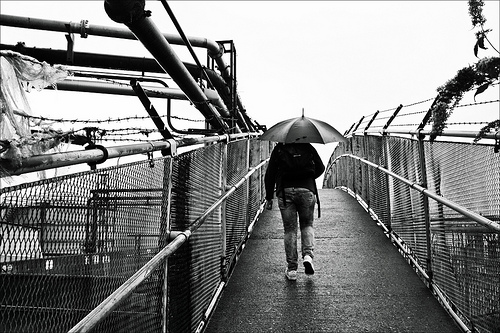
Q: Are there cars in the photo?
A: No, there are no cars.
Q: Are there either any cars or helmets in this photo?
A: No, there are no cars or helmets.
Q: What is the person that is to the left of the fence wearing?
A: The person is wearing jeans.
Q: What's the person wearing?
A: The person is wearing jeans.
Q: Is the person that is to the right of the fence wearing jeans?
A: Yes, the person is wearing jeans.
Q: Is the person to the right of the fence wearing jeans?
A: Yes, the person is wearing jeans.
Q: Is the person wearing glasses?
A: No, the person is wearing jeans.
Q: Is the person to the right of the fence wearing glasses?
A: No, the person is wearing jeans.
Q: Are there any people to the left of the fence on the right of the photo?
A: Yes, there is a person to the left of the fence.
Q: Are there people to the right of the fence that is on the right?
A: No, the person is to the left of the fence.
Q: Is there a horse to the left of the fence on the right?
A: No, there is a person to the left of the fence.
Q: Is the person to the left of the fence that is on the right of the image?
A: Yes, the person is to the left of the fence.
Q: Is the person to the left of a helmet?
A: No, the person is to the left of the fence.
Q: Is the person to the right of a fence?
A: No, the person is to the left of a fence.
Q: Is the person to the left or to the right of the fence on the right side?
A: The person is to the left of the fence.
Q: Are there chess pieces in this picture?
A: No, there are no chess pieces.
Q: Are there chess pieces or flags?
A: No, there are no chess pieces or flags.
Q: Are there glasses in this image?
A: No, there are no glasses.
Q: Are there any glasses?
A: No, there are no glasses.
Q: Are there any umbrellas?
A: Yes, there is an umbrella.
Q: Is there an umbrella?
A: Yes, there is an umbrella.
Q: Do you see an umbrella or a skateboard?
A: Yes, there is an umbrella.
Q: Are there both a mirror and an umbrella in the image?
A: No, there is an umbrella but no mirrors.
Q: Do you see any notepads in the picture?
A: No, there are no notepads.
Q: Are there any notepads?
A: No, there are no notepads.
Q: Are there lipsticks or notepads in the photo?
A: No, there are no notepads or lipsticks.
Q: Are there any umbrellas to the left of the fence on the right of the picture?
A: Yes, there is an umbrella to the left of the fence.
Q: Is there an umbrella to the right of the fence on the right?
A: No, the umbrella is to the left of the fence.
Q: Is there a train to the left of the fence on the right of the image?
A: No, there is an umbrella to the left of the fence.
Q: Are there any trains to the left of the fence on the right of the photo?
A: No, there is an umbrella to the left of the fence.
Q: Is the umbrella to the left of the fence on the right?
A: Yes, the umbrella is to the left of the fence.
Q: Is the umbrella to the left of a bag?
A: No, the umbrella is to the left of the fence.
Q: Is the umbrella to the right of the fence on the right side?
A: No, the umbrella is to the left of the fence.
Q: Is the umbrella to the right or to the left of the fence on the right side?
A: The umbrella is to the left of the fence.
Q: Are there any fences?
A: Yes, there is a fence.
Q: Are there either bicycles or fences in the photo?
A: Yes, there is a fence.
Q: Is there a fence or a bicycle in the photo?
A: Yes, there is a fence.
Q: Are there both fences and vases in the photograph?
A: No, there is a fence but no vases.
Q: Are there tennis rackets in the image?
A: No, there are no tennis rackets.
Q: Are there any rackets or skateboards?
A: No, there are no rackets or skateboards.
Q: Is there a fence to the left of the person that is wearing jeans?
A: Yes, there is a fence to the left of the person.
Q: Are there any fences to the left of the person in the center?
A: Yes, there is a fence to the left of the person.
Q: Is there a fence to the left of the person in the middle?
A: Yes, there is a fence to the left of the person.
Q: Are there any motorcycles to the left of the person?
A: No, there is a fence to the left of the person.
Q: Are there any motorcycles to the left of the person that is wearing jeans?
A: No, there is a fence to the left of the person.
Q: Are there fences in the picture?
A: Yes, there is a fence.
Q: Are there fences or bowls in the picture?
A: Yes, there is a fence.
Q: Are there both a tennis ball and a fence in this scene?
A: No, there is a fence but no tennis balls.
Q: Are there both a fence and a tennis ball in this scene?
A: No, there is a fence but no tennis balls.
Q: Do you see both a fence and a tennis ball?
A: No, there is a fence but no tennis balls.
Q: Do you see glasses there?
A: No, there are no glasses.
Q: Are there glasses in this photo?
A: No, there are no glasses.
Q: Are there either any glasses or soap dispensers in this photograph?
A: No, there are no glasses or soap dispensers.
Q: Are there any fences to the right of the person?
A: Yes, there is a fence to the right of the person.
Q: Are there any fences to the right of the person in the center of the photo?
A: Yes, there is a fence to the right of the person.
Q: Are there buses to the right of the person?
A: No, there is a fence to the right of the person.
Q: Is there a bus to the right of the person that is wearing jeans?
A: No, there is a fence to the right of the person.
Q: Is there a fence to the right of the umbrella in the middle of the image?
A: Yes, there is a fence to the right of the umbrella.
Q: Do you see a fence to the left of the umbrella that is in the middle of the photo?
A: No, the fence is to the right of the umbrella.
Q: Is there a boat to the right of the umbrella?
A: No, there is a fence to the right of the umbrella.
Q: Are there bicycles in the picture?
A: No, there are no bicycles.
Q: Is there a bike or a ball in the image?
A: No, there are no bikes or balls.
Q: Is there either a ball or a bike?
A: No, there are no bikes or balls.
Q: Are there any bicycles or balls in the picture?
A: No, there are no bicycles or balls.